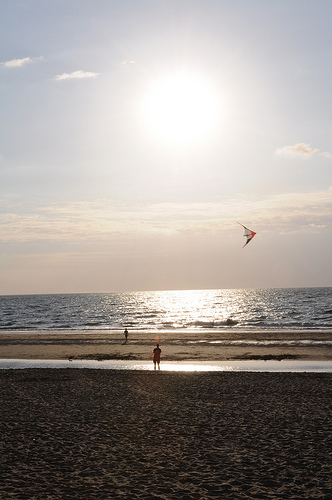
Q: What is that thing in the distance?
A: A flying kite.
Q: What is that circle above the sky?
A: The sun.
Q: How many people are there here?
A: Two.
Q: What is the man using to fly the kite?
A: A wire.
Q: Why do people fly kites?
A: For fun.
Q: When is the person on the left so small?
A: It is a child.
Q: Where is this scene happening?
A: At a beach.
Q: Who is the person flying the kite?
A: An adult.